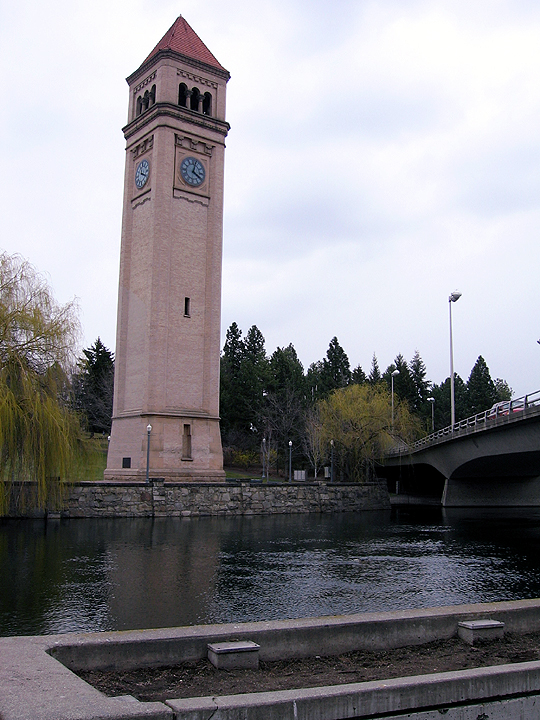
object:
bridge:
[374, 392, 540, 506]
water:
[0, 503, 540, 609]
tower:
[104, 14, 231, 484]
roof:
[130, 14, 231, 78]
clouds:
[0, 0, 540, 405]